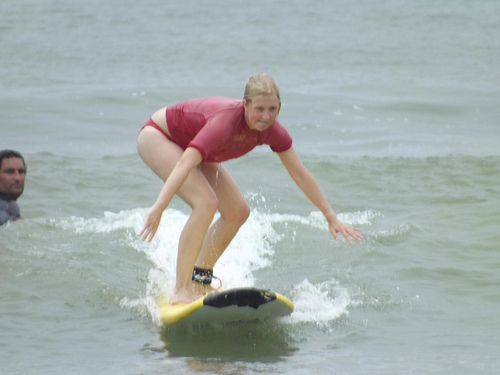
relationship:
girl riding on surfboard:
[131, 73, 361, 288] [149, 281, 294, 329]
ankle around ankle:
[192, 265, 214, 284] [188, 262, 219, 293]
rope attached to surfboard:
[207, 271, 224, 298] [149, 281, 294, 329]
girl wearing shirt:
[131, 73, 361, 288] [164, 94, 295, 159]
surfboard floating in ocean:
[149, 281, 294, 329] [1, 1, 496, 374]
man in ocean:
[1, 149, 26, 228] [1, 1, 496, 374]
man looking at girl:
[1, 149, 26, 228] [131, 73, 361, 288]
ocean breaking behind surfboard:
[1, 1, 496, 374] [149, 281, 294, 329]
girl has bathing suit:
[131, 73, 361, 288] [135, 117, 178, 147]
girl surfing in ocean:
[131, 73, 361, 288] [1, 1, 496, 374]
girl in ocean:
[131, 73, 361, 288] [1, 1, 496, 374]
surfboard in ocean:
[149, 281, 294, 329] [1, 1, 496, 374]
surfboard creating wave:
[149, 281, 294, 329] [118, 199, 288, 302]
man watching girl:
[1, 149, 26, 228] [131, 73, 361, 288]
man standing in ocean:
[1, 149, 26, 228] [1, 1, 496, 374]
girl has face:
[131, 73, 361, 288] [246, 93, 279, 134]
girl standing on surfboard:
[131, 73, 361, 288] [149, 281, 294, 329]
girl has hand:
[131, 73, 361, 288] [143, 209, 162, 242]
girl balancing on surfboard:
[131, 73, 361, 288] [149, 281, 294, 329]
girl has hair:
[131, 73, 361, 288] [244, 72, 279, 106]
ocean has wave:
[1, 1, 496, 374] [9, 211, 458, 329]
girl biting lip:
[131, 73, 361, 288] [258, 120, 271, 125]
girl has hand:
[131, 73, 361, 288] [327, 220, 362, 244]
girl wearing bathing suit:
[131, 73, 361, 288] [135, 117, 178, 147]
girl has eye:
[131, 73, 361, 288] [255, 102, 266, 116]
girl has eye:
[131, 73, 361, 288] [268, 106, 277, 114]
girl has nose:
[131, 73, 361, 288] [261, 108, 271, 124]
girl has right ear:
[131, 73, 361, 288] [239, 97, 249, 113]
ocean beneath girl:
[1, 1, 496, 374] [131, 73, 361, 288]